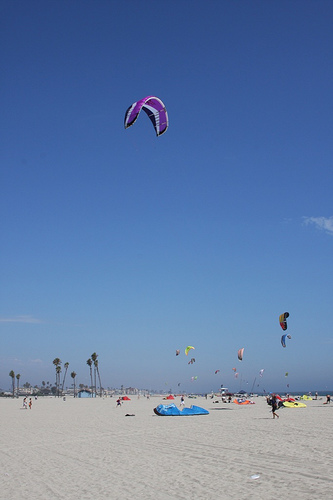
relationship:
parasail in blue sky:
[260, 307, 299, 337] [0, 0, 332, 396]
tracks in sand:
[57, 430, 332, 483] [0, 392, 332, 498]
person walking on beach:
[178, 392, 186, 407] [4, 392, 332, 498]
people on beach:
[18, 391, 331, 421] [4, 392, 332, 498]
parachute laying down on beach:
[100, 67, 197, 155] [4, 392, 332, 498]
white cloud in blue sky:
[298, 212, 332, 234] [1, 0, 332, 391]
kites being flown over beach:
[117, 81, 304, 390] [4, 392, 332, 498]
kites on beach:
[165, 306, 301, 384] [4, 392, 332, 498]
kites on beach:
[121, 89, 170, 138] [4, 392, 332, 498]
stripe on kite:
[125, 93, 164, 133] [124, 93, 170, 137]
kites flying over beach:
[105, 83, 320, 388] [4, 392, 332, 498]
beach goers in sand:
[201, 389, 330, 414] [1, 393, 332, 425]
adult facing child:
[20, 395, 28, 411] [27, 397, 34, 409]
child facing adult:
[27, 397, 34, 409] [20, 395, 28, 411]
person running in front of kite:
[113, 396, 125, 410] [121, 395, 132, 400]